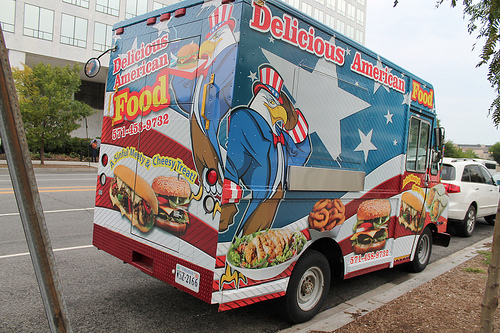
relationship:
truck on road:
[81, 0, 457, 315] [5, 167, 147, 331]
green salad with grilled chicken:
[222, 230, 308, 270] [218, 229, 302, 261]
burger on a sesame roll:
[150, 170, 194, 238] [155, 172, 193, 200]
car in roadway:
[435, 156, 497, 239] [0, 169, 497, 331]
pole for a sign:
[1, 32, 75, 331] [237, 10, 467, 106]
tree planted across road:
[10, 47, 87, 187] [5, 167, 147, 331]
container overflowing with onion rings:
[308, 222, 342, 238] [307, 198, 346, 230]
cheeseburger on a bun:
[353, 216, 391, 245] [351, 200, 392, 255]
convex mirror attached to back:
[83, 45, 113, 78] [93, 5, 233, 302]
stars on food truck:
[247, 19, 416, 168] [220, 1, 426, 187]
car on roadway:
[425, 135, 497, 242] [0, 169, 497, 331]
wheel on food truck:
[270, 245, 333, 326] [91, 1, 449, 317]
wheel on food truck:
[407, 228, 435, 277] [91, 1, 449, 317]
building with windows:
[9, 6, 372, 68] [1, 0, 119, 55]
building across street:
[9, 6, 372, 68] [2, 174, 488, 331]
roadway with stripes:
[0, 169, 497, 331] [2, 185, 95, 195]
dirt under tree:
[328, 245, 495, 330] [390, 2, 499, 332]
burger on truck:
[150, 174, 192, 234] [81, 0, 457, 315]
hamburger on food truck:
[355, 193, 390, 253] [91, 1, 449, 317]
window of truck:
[285, 59, 379, 205] [79, 12, 460, 282]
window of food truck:
[403, 113, 432, 173] [91, 1, 449, 317]